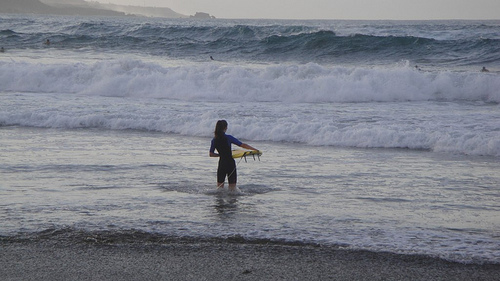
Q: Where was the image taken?
A: It was taken at the sea.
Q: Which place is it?
A: It is a sea.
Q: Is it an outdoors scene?
A: Yes, it is outdoors.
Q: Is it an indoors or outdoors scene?
A: It is outdoors.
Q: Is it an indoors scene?
A: No, it is outdoors.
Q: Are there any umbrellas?
A: No, there are no umbrellas.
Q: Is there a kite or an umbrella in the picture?
A: No, there are no umbrellas or kites.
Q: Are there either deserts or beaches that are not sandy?
A: No, there is a beach but it is sandy.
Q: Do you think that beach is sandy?
A: Yes, the beach is sandy.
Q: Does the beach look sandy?
A: Yes, the beach is sandy.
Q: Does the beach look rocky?
A: No, the beach is sandy.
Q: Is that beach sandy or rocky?
A: The beach is sandy.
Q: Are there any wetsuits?
A: Yes, there is a wetsuit.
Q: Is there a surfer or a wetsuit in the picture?
A: Yes, there is a wetsuit.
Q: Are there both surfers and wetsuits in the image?
A: Yes, there are both a wetsuit and a surfer.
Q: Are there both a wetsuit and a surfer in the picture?
A: Yes, there are both a wetsuit and a surfer.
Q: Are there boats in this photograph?
A: No, there are no boats.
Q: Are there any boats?
A: No, there are no boats.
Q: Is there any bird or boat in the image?
A: No, there are no boats or birds.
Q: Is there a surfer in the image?
A: Yes, there is a surfer.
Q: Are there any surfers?
A: Yes, there is a surfer.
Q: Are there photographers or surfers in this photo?
A: Yes, there is a surfer.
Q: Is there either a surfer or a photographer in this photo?
A: Yes, there is a surfer.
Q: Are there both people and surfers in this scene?
A: Yes, there are both a surfer and people.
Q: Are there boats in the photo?
A: No, there are no boats.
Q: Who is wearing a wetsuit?
A: The surfer is wearing a wetsuit.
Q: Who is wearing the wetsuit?
A: The surfer is wearing a wetsuit.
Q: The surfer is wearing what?
A: The surfer is wearing a wetsuit.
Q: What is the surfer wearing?
A: The surfer is wearing a wetsuit.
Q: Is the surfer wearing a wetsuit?
A: Yes, the surfer is wearing a wetsuit.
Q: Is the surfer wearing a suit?
A: No, the surfer is wearing a wetsuit.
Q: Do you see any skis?
A: No, there are no skis.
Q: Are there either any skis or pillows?
A: No, there are no skis or pillows.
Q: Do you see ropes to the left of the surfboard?
A: Yes, there is a rope to the left of the surfboard.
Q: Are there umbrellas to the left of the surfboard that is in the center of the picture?
A: No, there is a rope to the left of the surfboard.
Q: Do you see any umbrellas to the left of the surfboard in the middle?
A: No, there is a rope to the left of the surfboard.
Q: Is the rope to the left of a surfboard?
A: Yes, the rope is to the left of a surfboard.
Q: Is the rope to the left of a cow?
A: No, the rope is to the left of a surfboard.